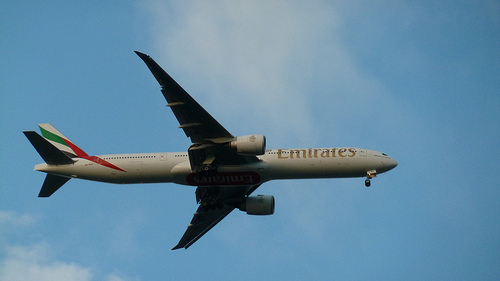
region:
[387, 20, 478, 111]
a portion of blue sky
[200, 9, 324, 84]
clouds in the sky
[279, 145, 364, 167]
name of airline carrier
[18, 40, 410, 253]
an airplane in sky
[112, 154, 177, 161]
passenger windows in airplane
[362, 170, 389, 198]
front wheel on airplane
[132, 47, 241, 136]
wing portion of airplane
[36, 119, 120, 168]
white, green, and red colors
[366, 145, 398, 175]
front part of airplane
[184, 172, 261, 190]
wording on underside of airplane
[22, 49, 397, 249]
A jetliner with Emirates on the side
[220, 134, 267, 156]
The right jet engine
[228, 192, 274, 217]
The left jet engine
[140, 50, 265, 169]
The right wing of a jetliner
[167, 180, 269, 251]
The left wing of a jetliner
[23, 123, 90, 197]
The tail of a jetliner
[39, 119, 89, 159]
The vertical stabilizer of a jetliner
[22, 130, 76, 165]
The right horizontal stabilizer of a jetliner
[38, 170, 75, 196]
The left horizontal stabilizer of a jetliner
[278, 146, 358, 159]
Writing on a jetliner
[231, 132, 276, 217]
Engines on an airplane that is in flight.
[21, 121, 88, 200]
Tail end of an airplane.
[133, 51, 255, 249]
Wings on a mostly gray colored airplane.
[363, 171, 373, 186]
Landing gear on the front of an airplane.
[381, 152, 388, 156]
Side windshield of a mostly gray colored plane.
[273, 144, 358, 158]
The word EMIRARES on the front side of a plane.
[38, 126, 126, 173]
Green and red stripes on the end of an airplane.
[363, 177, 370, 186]
Two front wheels on an airplane in flight.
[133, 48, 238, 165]
Wing that is closest to the camera.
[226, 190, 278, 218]
Engine on the other side of the plane.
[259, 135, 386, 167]
United Emirates airline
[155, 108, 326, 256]
twin engine jet plane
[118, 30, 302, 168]
long airplane wings providing lift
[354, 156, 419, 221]
retracting airplane gear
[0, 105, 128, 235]
airplane tail section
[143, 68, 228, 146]
deployed wing control surfaces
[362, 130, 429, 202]
cockpit windows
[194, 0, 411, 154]
white clouds in the background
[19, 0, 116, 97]
blue sky in the background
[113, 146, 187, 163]
passenger windows in the main fuselage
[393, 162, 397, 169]
front part of a plane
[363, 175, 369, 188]
front wheels of a plane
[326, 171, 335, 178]
bottom part of a plane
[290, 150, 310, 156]
side part of a plane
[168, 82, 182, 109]
wing of a plane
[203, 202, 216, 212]
back wheels of a plane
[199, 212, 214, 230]
left wing of a plane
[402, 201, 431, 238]
section of the blue sky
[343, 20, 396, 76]
part of the sky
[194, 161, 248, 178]
section of a flying plane